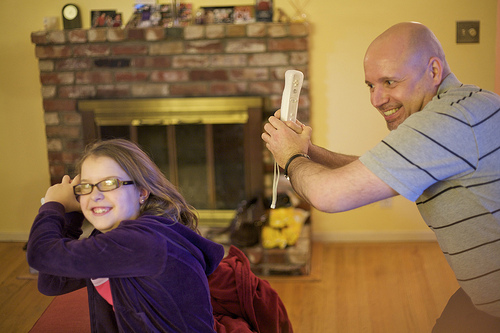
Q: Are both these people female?
A: No, they are both male and female.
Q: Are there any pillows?
A: No, there are no pillows.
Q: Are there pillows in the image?
A: No, there are no pillows.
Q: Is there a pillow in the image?
A: No, there are no pillows.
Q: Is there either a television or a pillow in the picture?
A: No, there are no pillows or televisions.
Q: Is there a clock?
A: Yes, there is a clock.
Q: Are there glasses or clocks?
A: Yes, there is a clock.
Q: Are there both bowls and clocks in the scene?
A: No, there is a clock but no bowls.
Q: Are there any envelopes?
A: No, there are no envelopes.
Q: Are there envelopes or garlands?
A: No, there are no envelopes or garlands.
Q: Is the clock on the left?
A: Yes, the clock is on the left of the image.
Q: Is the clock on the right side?
A: No, the clock is on the left of the image.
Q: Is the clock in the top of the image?
A: Yes, the clock is in the top of the image.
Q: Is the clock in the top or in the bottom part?
A: The clock is in the top of the image.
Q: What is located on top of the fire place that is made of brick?
A: The clock is on top of the fireplace.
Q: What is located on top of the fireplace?
A: The clock is on top of the fireplace.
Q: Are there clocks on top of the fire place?
A: Yes, there is a clock on top of the fire place.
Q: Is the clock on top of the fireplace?
A: Yes, the clock is on top of the fireplace.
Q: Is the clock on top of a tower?
A: No, the clock is on top of the fireplace.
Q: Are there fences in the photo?
A: No, there are no fences.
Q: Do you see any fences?
A: No, there are no fences.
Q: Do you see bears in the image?
A: No, there are no bears.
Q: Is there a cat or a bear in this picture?
A: No, there are no bears or cats.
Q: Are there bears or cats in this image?
A: No, there are no bears or cats.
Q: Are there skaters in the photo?
A: No, there are no skaters.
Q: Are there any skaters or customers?
A: No, there are no skaters or customers.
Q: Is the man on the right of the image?
A: Yes, the man is on the right of the image.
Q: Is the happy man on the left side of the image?
A: No, the man is on the right of the image.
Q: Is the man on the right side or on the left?
A: The man is on the right of the image.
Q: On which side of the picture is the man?
A: The man is on the right of the image.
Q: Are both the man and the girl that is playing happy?
A: Yes, both the man and the girl are happy.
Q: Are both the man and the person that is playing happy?
A: Yes, both the man and the girl are happy.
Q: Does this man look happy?
A: Yes, the man is happy.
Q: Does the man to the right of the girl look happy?
A: Yes, the man is happy.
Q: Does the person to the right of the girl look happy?
A: Yes, the man is happy.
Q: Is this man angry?
A: No, the man is happy.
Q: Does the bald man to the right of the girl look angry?
A: No, the man is happy.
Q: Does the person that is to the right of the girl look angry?
A: No, the man is happy.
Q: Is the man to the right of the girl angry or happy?
A: The man is happy.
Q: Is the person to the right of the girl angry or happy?
A: The man is happy.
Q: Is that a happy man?
A: Yes, that is a happy man.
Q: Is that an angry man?
A: No, that is a happy man.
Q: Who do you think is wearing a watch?
A: The man is wearing a watch.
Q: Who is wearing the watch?
A: The man is wearing a watch.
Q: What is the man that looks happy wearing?
A: The man is wearing a watch.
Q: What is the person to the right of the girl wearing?
A: The man is wearing a watch.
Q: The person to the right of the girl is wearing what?
A: The man is wearing a watch.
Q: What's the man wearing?
A: The man is wearing a watch.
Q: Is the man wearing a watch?
A: Yes, the man is wearing a watch.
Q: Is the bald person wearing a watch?
A: Yes, the man is wearing a watch.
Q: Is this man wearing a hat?
A: No, the man is wearing a watch.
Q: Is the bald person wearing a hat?
A: No, the man is wearing a watch.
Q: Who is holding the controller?
A: The man is holding the controller.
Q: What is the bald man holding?
A: The man is holding the controller.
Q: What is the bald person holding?
A: The man is holding the controller.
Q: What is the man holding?
A: The man is holding the controller.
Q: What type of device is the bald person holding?
A: The man is holding the controller.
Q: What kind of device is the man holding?
A: The man is holding the controller.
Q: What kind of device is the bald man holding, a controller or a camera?
A: The man is holding a controller.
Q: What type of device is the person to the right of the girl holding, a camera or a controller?
A: The man is holding a controller.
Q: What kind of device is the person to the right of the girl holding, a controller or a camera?
A: The man is holding a controller.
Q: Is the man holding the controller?
A: Yes, the man is holding the controller.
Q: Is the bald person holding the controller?
A: Yes, the man is holding the controller.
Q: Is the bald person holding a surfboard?
A: No, the man is holding the controller.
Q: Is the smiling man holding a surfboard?
A: No, the man is holding the controller.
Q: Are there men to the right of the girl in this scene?
A: Yes, there is a man to the right of the girl.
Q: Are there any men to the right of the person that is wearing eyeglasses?
A: Yes, there is a man to the right of the girl.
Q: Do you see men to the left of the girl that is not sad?
A: No, the man is to the right of the girl.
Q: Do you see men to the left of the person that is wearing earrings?
A: No, the man is to the right of the girl.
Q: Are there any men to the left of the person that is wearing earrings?
A: No, the man is to the right of the girl.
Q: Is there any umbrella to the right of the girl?
A: No, there is a man to the right of the girl.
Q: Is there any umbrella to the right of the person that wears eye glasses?
A: No, there is a man to the right of the girl.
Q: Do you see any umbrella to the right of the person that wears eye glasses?
A: No, there is a man to the right of the girl.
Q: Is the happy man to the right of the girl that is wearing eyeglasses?
A: Yes, the man is to the right of the girl.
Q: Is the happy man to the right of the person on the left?
A: Yes, the man is to the right of the girl.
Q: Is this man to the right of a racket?
A: No, the man is to the right of the girl.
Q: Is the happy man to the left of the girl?
A: No, the man is to the right of the girl.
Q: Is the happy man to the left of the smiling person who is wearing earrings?
A: No, the man is to the right of the girl.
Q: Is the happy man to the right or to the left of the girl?
A: The man is to the right of the girl.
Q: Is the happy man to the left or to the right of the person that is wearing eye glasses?
A: The man is to the right of the girl.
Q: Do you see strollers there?
A: No, there are no strollers.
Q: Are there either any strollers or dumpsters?
A: No, there are no strollers or dumpsters.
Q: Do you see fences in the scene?
A: No, there are no fences.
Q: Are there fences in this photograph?
A: No, there are no fences.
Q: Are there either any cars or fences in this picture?
A: No, there are no fences or cars.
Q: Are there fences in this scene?
A: No, there are no fences.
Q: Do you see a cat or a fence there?
A: No, there are no fences or cats.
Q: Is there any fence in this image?
A: No, there are no fences.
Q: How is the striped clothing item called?
A: The clothing item is a shirt.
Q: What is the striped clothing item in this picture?
A: The clothing item is a shirt.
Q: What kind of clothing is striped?
A: The clothing is a shirt.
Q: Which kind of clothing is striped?
A: The clothing is a shirt.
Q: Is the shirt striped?
A: Yes, the shirt is striped.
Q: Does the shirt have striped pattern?
A: Yes, the shirt is striped.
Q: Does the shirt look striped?
A: Yes, the shirt is striped.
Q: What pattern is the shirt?
A: The shirt is striped.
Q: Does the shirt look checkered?
A: No, the shirt is striped.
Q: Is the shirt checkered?
A: No, the shirt is striped.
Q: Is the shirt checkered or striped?
A: The shirt is striped.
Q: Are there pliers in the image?
A: No, there are no pliers.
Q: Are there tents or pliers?
A: No, there are no pliers or tents.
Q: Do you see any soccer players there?
A: No, there are no soccer players.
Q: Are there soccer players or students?
A: No, there are no soccer players or students.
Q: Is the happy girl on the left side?
A: Yes, the girl is on the left of the image.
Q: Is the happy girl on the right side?
A: No, the girl is on the left of the image.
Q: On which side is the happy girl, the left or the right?
A: The girl is on the left of the image.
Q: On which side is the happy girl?
A: The girl is on the left of the image.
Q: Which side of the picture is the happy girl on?
A: The girl is on the left of the image.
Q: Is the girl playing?
A: Yes, the girl is playing.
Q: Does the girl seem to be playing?
A: Yes, the girl is playing.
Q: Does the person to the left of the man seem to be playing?
A: Yes, the girl is playing.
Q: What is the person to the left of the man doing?
A: The girl is playing.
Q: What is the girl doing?
A: The girl is playing.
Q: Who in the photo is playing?
A: The girl is playing.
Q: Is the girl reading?
A: No, the girl is playing.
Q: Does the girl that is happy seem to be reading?
A: No, the girl is playing.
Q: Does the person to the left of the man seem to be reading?
A: No, the girl is playing.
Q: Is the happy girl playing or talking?
A: The girl is playing.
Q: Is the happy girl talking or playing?
A: The girl is playing.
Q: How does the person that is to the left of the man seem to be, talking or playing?
A: The girl is playing.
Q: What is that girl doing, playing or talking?
A: The girl is playing.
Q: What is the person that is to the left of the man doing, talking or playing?
A: The girl is playing.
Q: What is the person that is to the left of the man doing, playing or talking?
A: The girl is playing.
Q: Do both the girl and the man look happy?
A: Yes, both the girl and the man are happy.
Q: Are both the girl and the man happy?
A: Yes, both the girl and the man are happy.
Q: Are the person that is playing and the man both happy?
A: Yes, both the girl and the man are happy.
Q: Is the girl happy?
A: Yes, the girl is happy.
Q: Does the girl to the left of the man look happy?
A: Yes, the girl is happy.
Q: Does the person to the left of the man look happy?
A: Yes, the girl is happy.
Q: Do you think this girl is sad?
A: No, the girl is happy.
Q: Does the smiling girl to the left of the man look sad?
A: No, the girl is happy.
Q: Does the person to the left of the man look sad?
A: No, the girl is happy.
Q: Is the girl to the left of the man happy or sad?
A: The girl is happy.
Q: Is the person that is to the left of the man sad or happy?
A: The girl is happy.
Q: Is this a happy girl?
A: Yes, this is a happy girl.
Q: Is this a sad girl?
A: No, this is a happy girl.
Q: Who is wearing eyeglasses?
A: The girl is wearing eyeglasses.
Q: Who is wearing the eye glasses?
A: The girl is wearing eyeglasses.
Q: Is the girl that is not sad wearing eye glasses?
A: Yes, the girl is wearing eye glasses.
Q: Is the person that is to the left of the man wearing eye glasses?
A: Yes, the girl is wearing eye glasses.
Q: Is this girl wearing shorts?
A: No, the girl is wearing eye glasses.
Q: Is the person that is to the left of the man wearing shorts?
A: No, the girl is wearing eye glasses.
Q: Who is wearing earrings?
A: The girl is wearing earrings.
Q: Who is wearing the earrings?
A: The girl is wearing earrings.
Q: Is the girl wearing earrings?
A: Yes, the girl is wearing earrings.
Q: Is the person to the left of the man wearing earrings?
A: Yes, the girl is wearing earrings.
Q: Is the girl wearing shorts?
A: No, the girl is wearing earrings.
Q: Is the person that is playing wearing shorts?
A: No, the girl is wearing earrings.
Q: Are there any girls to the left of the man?
A: Yes, there is a girl to the left of the man.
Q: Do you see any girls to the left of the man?
A: Yes, there is a girl to the left of the man.